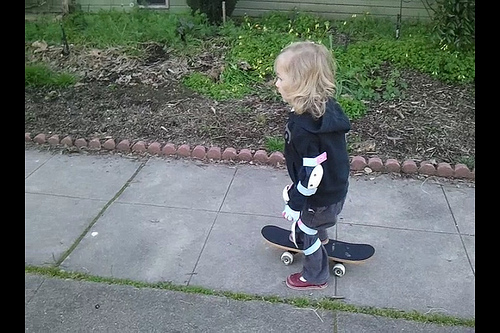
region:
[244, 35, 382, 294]
Little girl on skateboard.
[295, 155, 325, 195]
Elbow pad over little girl's elbow.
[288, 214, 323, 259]
Knee pad over little girl's knee.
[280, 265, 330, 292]
Brown shoe on little girl's foot.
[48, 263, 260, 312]
Grass growing along edge of sidewalk.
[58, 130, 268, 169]
Landscaping bricks along edge of sidewalk.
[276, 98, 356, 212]
Little girl wearing black jacket with hood.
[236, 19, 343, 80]
Yellow flowers growing in yard on side of house.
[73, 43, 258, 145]
Dead leaves and dirt on side of house.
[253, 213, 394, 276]
Black skateboard under little girl's foot.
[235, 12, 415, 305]
child on a skateboard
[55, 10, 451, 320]
child skating on sidewalk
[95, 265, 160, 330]
grass growing between cracks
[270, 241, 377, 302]
shoes are red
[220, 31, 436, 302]
the hair is blonde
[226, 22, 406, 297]
the jacket is black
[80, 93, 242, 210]
decorative brick trim on sidewalk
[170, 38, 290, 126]
the flowers are yellow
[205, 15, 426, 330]
the activity is skating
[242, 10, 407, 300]
the hair is wavy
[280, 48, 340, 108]
The child's blonde hair.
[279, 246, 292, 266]
The front wheel of the skateboard.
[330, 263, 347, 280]
The back wheel of the skateboard.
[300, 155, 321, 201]
The elbow pads on the child's arm.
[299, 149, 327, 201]
The straps of the elbow pad.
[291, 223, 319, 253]
The knee pad on the child's left leg.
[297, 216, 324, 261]
The straps of the knee pad on the child's left leg.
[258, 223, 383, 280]
The skateboard the child is riding.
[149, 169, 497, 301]
The sidewalk area where the child is skateboarding.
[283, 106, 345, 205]
The black hoody the child is wearing.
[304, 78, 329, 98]
hair of a small girl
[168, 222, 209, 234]
edge of a path way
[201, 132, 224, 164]
edge of a flower garden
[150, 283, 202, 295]
grass o the pathway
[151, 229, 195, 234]
part of a walk way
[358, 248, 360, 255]
back part of a skate board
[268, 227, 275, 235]
front part of skate board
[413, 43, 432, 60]
green vegetation along the road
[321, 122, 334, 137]
part of a girls jumper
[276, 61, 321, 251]
a small girl skating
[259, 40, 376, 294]
Small child trying to ride a skateboard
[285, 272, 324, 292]
Red baby jane shoe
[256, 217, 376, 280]
Small black skateboard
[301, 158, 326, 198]
White elbow pad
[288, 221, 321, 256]
Straps for knee pad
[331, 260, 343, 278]
White skateboard wheel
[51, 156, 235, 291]
Concrete sidewalk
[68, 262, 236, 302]
Grass growing in sidewalk crack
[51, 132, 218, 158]
Red round brick yard border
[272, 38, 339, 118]
Long blonde wavy hair